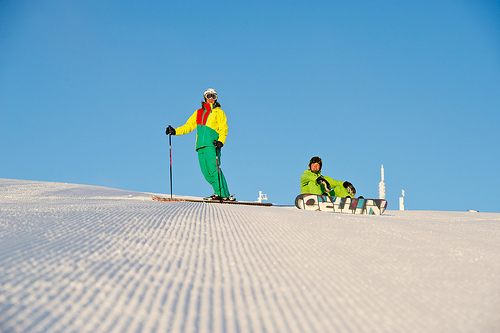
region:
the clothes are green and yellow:
[184, 108, 246, 187]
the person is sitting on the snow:
[277, 152, 432, 262]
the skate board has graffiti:
[284, 185, 397, 220]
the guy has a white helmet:
[200, 82, 237, 111]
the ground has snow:
[137, 250, 333, 287]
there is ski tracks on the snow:
[168, 233, 371, 316]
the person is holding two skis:
[151, 125, 253, 203]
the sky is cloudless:
[275, 93, 462, 152]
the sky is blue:
[318, 96, 496, 153]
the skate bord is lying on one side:
[287, 184, 403, 216]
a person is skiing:
[158, 89, 272, 205]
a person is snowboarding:
[297, 156, 388, 217]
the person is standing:
[172, 90, 235, 204]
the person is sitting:
[298, 156, 389, 215]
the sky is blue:
[0, 1, 499, 212]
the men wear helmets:
[202, 90, 324, 170]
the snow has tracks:
[1, 177, 499, 330]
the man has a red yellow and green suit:
[173, 101, 234, 197]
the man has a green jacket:
[300, 174, 350, 195]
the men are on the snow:
[166, 87, 386, 217]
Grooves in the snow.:
[48, 204, 233, 331]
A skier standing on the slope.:
[149, 76, 271, 208]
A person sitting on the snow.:
[294, 154, 394, 214]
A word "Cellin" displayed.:
[298, 192, 386, 217]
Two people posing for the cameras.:
[150, 73, 385, 213]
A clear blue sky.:
[230, 0, 497, 152]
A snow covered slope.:
[8, 180, 498, 330]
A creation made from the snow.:
[393, 163, 412, 218]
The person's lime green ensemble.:
[296, 170, 349, 195]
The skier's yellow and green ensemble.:
[175, 107, 237, 197]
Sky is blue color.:
[285, 66, 416, 122]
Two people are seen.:
[177, 75, 357, 225]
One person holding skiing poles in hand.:
[151, 76, 262, 214]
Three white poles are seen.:
[248, 157, 404, 213]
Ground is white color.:
[90, 221, 296, 284]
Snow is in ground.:
[55, 210, 275, 290]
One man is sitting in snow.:
[301, 158, 357, 209]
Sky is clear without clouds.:
[23, 8, 483, 88]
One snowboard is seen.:
[295, 187, 390, 214]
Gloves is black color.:
[159, 116, 230, 150]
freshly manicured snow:
[1, 207, 342, 331]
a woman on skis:
[152, 86, 274, 212]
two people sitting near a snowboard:
[290, 151, 390, 218]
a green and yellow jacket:
[176, 102, 228, 147]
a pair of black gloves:
[162, 122, 223, 156]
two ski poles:
[159, 123, 233, 205]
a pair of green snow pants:
[194, 137, 237, 199]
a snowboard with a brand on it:
[276, 190, 406, 216]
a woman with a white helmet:
[160, 81, 235, 208]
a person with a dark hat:
[292, 151, 334, 213]